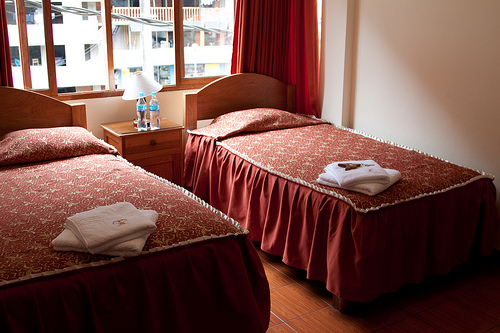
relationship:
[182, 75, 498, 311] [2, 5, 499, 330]
bed in room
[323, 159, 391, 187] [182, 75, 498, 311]
towel on bed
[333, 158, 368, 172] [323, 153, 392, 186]
emblem on towel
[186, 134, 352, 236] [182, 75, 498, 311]
skirt on bed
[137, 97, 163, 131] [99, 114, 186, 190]
bottles on night table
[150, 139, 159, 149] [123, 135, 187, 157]
knob on drawer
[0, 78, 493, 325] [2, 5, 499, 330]
two beds in room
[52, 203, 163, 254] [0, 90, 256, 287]
2 towels on bed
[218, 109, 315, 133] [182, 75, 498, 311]
pillow on bed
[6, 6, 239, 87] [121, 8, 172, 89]
windows facing building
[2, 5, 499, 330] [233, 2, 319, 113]
room has curtains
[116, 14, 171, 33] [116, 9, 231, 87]
cables seen outside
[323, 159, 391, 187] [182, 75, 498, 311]
towel seen on bed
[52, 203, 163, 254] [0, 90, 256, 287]
two towels on bed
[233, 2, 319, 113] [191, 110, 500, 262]
curtains coordinated with bedspread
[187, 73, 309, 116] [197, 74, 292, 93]
headboard has arch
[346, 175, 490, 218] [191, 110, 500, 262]
ribbing around bedspread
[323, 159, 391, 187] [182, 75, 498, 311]
towel on hotel bed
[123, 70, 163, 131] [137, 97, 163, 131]
lamp behind water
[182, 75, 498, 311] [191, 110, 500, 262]
hotel bed with red blanket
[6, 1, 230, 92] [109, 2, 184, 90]
view outside window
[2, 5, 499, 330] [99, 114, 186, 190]
bedroom has night table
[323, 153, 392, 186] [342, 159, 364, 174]
towel has anchor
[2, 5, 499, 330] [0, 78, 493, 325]
room has two beds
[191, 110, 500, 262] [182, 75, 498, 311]
comforter on bed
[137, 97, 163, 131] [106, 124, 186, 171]
two bottles on night table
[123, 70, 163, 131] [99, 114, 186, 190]
lamp on night table